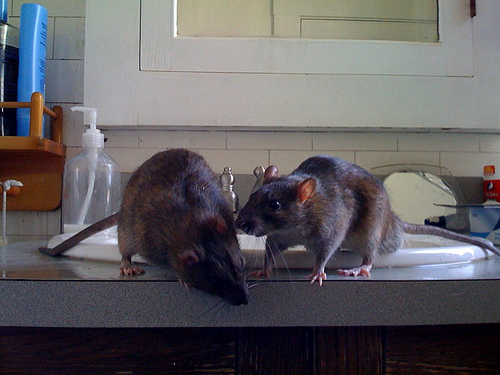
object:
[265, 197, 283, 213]
eye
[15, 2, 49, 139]
shampoo bottle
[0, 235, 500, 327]
counter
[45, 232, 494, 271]
sink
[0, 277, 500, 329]
ledge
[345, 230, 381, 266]
leg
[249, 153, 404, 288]
body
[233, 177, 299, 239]
face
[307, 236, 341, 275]
legs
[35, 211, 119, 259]
tail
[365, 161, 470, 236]
plate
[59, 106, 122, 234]
bottle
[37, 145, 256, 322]
rodent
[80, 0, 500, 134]
chest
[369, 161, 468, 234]
mirror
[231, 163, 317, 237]
head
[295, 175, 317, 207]
ear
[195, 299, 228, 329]
whisker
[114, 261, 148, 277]
foot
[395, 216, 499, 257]
tail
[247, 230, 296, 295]
wiskers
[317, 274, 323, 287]
toe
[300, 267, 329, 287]
foot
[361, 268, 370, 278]
toe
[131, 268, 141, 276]
toe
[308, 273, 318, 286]
toe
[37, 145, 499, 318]
two rats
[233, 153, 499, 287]
big rat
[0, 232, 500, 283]
counter top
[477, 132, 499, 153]
ceramic tile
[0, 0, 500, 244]
wall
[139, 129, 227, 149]
ceramic tile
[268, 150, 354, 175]
tile